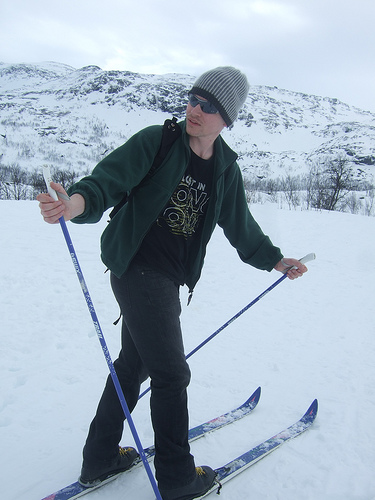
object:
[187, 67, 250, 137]
head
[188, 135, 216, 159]
neck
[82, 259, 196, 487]
pants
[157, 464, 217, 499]
boots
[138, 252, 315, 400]
ski pole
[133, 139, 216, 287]
tshirt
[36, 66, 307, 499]
man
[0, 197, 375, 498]
snow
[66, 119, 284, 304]
jacket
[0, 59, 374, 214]
mountains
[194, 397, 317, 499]
ski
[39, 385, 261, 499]
ski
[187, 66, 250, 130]
cap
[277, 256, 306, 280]
hand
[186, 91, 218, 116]
sunglasses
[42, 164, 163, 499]
pole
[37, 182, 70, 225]
hand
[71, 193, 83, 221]
wrist